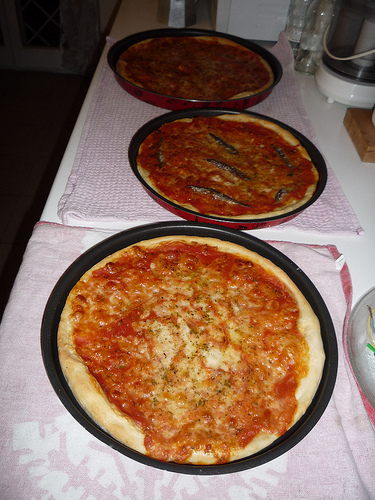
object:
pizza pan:
[126, 105, 329, 226]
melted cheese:
[94, 255, 290, 431]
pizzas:
[109, 26, 274, 98]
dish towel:
[55, 35, 364, 234]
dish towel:
[0, 222, 374, 497]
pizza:
[138, 109, 319, 220]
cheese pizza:
[54, 237, 329, 466]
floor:
[0, 18, 98, 326]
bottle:
[291, 2, 333, 78]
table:
[2, 2, 372, 497]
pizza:
[117, 32, 276, 101]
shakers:
[267, 3, 359, 95]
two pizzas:
[103, 21, 329, 224]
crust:
[250, 112, 291, 137]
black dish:
[35, 219, 340, 482]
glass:
[277, 0, 312, 54]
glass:
[291, 0, 336, 75]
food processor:
[311, 2, 374, 113]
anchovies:
[207, 130, 239, 155]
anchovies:
[206, 157, 249, 182]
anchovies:
[185, 184, 249, 208]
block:
[335, 94, 375, 162]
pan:
[104, 26, 284, 110]